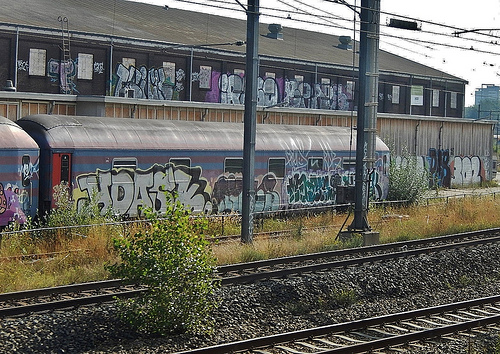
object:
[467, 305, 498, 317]
board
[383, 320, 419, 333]
wooden board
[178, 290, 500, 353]
tracks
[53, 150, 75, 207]
board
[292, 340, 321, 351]
wooden board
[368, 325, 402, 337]
board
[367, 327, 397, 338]
board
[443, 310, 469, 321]
board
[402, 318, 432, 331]
board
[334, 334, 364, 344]
board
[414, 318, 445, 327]
board